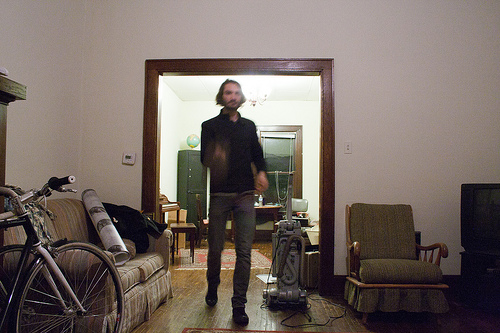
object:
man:
[200, 78, 270, 326]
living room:
[0, 0, 499, 333]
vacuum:
[263, 186, 309, 310]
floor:
[128, 237, 500, 333]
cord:
[259, 233, 346, 327]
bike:
[0, 175, 126, 333]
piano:
[158, 193, 180, 224]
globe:
[186, 134, 200, 148]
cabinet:
[177, 149, 208, 241]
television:
[460, 183, 500, 253]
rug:
[178, 248, 273, 270]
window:
[260, 130, 296, 212]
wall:
[156, 73, 321, 222]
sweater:
[200, 107, 267, 193]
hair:
[215, 78, 247, 106]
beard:
[221, 100, 245, 117]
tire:
[9, 242, 124, 333]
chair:
[345, 202, 449, 326]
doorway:
[141, 57, 335, 297]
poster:
[80, 188, 131, 266]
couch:
[2, 198, 173, 332]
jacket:
[84, 201, 168, 254]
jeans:
[206, 192, 255, 308]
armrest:
[416, 242, 448, 267]